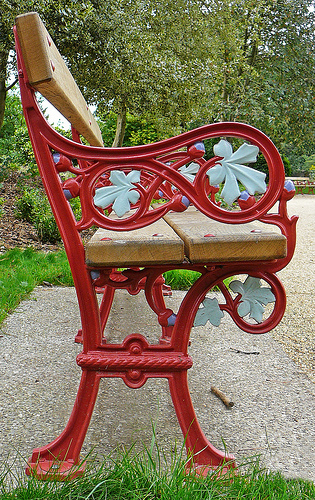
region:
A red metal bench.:
[28, 107, 295, 239]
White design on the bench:
[203, 140, 266, 204]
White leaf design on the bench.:
[188, 275, 276, 332]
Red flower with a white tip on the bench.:
[166, 193, 189, 215]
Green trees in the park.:
[137, 9, 301, 106]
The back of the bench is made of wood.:
[18, 5, 89, 107]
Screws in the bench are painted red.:
[198, 226, 266, 244]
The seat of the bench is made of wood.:
[85, 211, 268, 260]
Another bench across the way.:
[278, 167, 312, 193]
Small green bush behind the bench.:
[14, 191, 41, 232]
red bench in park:
[5, 6, 297, 424]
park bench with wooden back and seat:
[7, 3, 299, 273]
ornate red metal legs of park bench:
[7, 258, 251, 490]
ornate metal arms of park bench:
[15, 83, 295, 350]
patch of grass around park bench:
[0, 222, 255, 352]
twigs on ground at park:
[205, 337, 273, 429]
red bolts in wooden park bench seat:
[93, 234, 273, 271]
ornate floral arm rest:
[22, 116, 305, 275]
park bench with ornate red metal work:
[17, 83, 294, 353]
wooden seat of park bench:
[64, 154, 298, 297]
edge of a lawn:
[177, 472, 180, 477]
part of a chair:
[201, 444, 202, 447]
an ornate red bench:
[12, 10, 302, 486]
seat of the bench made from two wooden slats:
[86, 202, 288, 264]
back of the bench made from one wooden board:
[14, 11, 105, 148]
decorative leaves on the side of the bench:
[92, 139, 277, 331]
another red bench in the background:
[292, 176, 314, 195]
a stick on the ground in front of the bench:
[209, 383, 237, 408]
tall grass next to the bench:
[1, 438, 314, 499]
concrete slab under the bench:
[1, 282, 312, 494]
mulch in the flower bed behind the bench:
[1, 164, 75, 252]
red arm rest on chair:
[63, 119, 279, 225]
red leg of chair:
[23, 380, 104, 491]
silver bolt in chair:
[40, 461, 61, 474]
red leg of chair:
[164, 383, 263, 469]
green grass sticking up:
[72, 431, 188, 498]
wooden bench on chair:
[81, 237, 187, 263]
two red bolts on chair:
[94, 233, 168, 243]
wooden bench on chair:
[185, 233, 291, 262]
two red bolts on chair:
[199, 229, 266, 240]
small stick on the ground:
[211, 379, 231, 414]